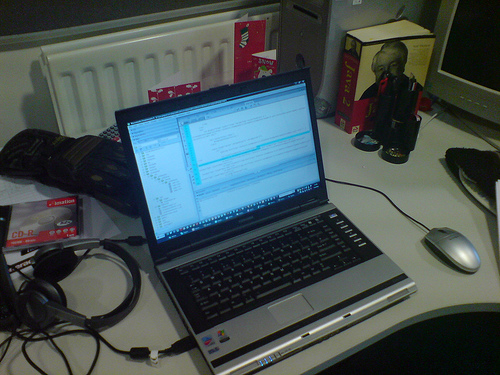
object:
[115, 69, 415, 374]
laptop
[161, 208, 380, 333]
keyboard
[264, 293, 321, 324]
touchpad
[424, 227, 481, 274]
mouse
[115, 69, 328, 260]
monitor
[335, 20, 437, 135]
book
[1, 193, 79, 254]
case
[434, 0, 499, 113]
monitor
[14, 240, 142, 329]
earphone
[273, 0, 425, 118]
desktop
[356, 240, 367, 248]
button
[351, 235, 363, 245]
button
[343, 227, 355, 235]
button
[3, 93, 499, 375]
table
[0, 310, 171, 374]
cable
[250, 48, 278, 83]
card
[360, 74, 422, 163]
holder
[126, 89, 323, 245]
document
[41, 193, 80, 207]
red label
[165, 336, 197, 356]
connector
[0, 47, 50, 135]
wall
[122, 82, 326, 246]
screen